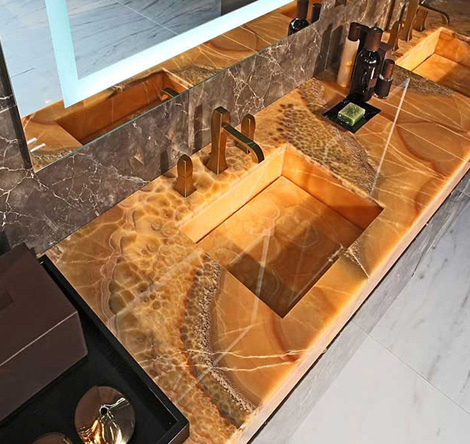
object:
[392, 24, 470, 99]
sink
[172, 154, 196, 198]
knob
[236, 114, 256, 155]
knob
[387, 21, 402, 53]
knob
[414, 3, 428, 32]
knob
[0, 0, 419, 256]
mirror wall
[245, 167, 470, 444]
floor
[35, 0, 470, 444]
counter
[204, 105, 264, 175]
faucet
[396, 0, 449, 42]
faucet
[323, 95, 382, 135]
soapdish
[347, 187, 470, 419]
tiles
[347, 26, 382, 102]
bottle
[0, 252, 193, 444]
tray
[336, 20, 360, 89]
bottle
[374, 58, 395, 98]
bottle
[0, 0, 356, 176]
mirror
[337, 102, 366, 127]
soap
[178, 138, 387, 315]
sink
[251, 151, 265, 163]
water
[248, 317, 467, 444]
tile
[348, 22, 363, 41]
cap